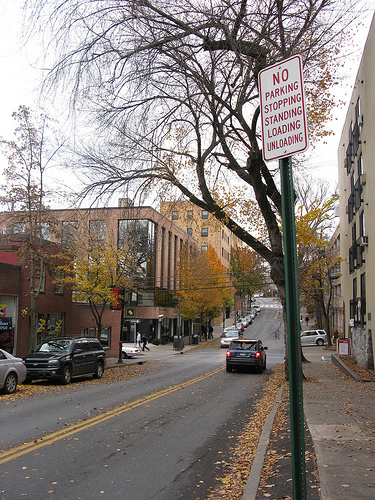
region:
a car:
[195, 291, 271, 424]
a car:
[128, 199, 302, 449]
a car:
[240, 323, 310, 422]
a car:
[178, 310, 294, 495]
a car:
[193, 177, 272, 489]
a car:
[204, 256, 347, 474]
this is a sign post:
[247, 47, 316, 489]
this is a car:
[212, 337, 283, 378]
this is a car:
[282, 324, 328, 348]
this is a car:
[22, 333, 108, 388]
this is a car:
[0, 349, 23, 387]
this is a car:
[212, 324, 240, 343]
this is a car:
[108, 327, 146, 359]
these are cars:
[234, 300, 264, 325]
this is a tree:
[66, 215, 126, 344]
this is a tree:
[164, 246, 235, 349]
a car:
[159, 228, 258, 457]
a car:
[219, 217, 266, 462]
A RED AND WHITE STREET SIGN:
[243, 48, 323, 168]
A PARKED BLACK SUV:
[20, 330, 116, 384]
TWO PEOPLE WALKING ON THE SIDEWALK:
[127, 326, 159, 357]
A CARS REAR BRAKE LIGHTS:
[221, 346, 262, 361]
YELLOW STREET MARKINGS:
[35, 375, 221, 428]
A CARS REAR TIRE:
[2, 366, 25, 395]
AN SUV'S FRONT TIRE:
[59, 359, 75, 385]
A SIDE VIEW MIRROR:
[66, 345, 88, 357]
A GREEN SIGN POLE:
[272, 165, 327, 495]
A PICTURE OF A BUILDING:
[152, 183, 242, 277]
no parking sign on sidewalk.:
[235, 56, 316, 164]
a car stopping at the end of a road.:
[213, 335, 288, 378]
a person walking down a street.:
[129, 322, 158, 363]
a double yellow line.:
[0, 301, 280, 466]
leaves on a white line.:
[214, 350, 293, 498]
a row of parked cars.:
[212, 295, 270, 357]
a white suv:
[274, 306, 329, 347]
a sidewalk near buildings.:
[284, 332, 373, 497]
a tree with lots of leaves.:
[46, 190, 138, 373]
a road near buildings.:
[0, 294, 303, 498]